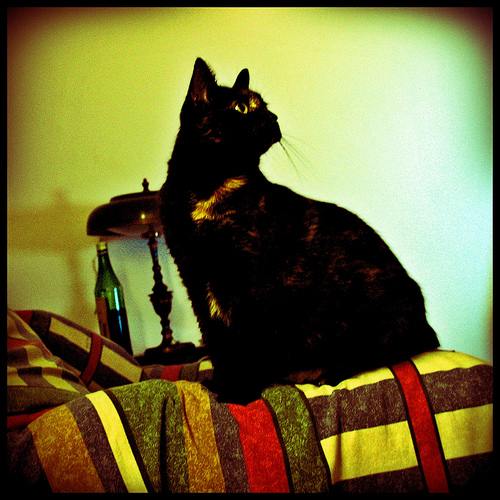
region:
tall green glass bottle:
[86, 238, 135, 363]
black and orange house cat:
[155, 49, 445, 408]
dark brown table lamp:
[56, 178, 205, 370]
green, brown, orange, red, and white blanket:
[2, 300, 498, 492]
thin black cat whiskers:
[270, 125, 314, 184]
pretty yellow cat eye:
[230, 97, 249, 116]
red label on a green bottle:
[92, 291, 109, 340]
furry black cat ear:
[182, 54, 220, 109]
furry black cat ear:
[230, 60, 255, 87]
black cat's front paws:
[203, 365, 271, 407]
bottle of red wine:
[86, 240, 134, 341]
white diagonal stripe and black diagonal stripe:
[81, 390, 162, 494]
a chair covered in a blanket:
[6, 310, 495, 468]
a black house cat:
[157, 55, 442, 390]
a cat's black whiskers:
[264, 109, 329, 179]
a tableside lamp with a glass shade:
[85, 172, 195, 366]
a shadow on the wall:
[6, 178, 99, 323]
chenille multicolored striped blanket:
[23, 370, 496, 497]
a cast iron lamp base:
[132, 235, 198, 364]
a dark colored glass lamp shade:
[75, 175, 175, 244]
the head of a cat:
[159, 63, 291, 172]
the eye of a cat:
[216, 94, 273, 128]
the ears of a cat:
[171, 60, 296, 182]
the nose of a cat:
[231, 100, 294, 164]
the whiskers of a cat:
[250, 66, 356, 205]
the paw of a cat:
[179, 314, 305, 411]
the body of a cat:
[174, 176, 404, 442]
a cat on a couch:
[128, 100, 417, 417]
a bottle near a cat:
[80, 232, 151, 380]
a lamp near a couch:
[81, 146, 238, 357]